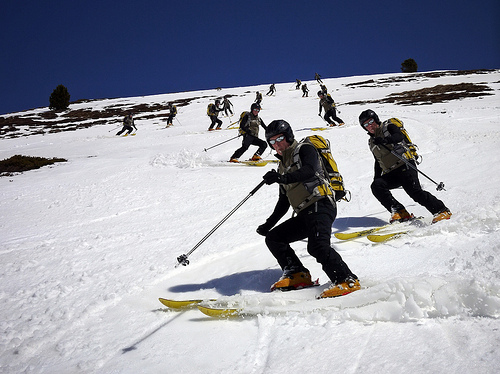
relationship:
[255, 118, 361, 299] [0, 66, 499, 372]
man skiing down a hill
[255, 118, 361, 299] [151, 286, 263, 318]
man on ski slope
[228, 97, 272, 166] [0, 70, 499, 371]
person on a ski slope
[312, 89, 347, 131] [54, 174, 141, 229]
person on a ski slope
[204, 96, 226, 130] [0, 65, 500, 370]
person on a ski slope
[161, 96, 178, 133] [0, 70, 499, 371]
person on a ski slope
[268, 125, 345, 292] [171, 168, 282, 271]
man holding pole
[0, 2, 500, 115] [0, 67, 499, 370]
sky above mountain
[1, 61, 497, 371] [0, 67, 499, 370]
snow on mountain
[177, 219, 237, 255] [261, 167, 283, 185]
pole in hand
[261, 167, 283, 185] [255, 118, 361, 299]
hand of man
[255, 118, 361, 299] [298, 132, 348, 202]
man carrying a backpack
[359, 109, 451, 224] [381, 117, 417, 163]
man carrying a backpack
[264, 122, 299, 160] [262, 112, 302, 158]
helmet on head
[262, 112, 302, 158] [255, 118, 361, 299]
head of man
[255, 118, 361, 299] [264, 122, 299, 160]
man wearing a helmet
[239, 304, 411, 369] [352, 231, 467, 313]
snow on ground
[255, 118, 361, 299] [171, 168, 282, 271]
man holding pole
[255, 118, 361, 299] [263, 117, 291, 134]
man wearing helmet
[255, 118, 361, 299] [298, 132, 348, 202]
man wearing backpack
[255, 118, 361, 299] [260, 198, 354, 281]
man wearing pants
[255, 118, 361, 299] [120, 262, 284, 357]
man casting shadow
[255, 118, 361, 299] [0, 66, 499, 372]
man skiing down hill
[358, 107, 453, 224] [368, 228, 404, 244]
man wearing yellow ski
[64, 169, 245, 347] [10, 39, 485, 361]
snow covering hill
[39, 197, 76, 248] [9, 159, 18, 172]
snow reveals grass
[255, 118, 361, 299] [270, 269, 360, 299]
man wearing shoes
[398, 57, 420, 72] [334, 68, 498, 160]
tree on mountain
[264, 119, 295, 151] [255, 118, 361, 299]
helmet on man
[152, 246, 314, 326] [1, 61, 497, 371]
shadow near snow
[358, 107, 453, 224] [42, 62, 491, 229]
man on slope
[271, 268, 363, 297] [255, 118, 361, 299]
boots on man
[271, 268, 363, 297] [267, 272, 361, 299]
boots on feet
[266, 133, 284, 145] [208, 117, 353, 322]
ski glasses on man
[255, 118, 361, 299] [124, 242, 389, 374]
man who skiing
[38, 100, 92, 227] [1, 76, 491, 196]
tree in background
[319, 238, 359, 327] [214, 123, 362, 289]
snow boots on man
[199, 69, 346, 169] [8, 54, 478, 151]
people in background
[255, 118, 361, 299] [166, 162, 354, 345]
man at an angle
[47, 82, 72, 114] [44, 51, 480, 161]
tree in background